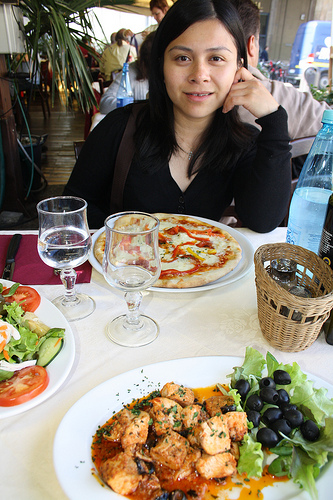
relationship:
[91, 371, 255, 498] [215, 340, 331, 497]
chicken dish with salad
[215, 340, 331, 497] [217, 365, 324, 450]
salad and black olives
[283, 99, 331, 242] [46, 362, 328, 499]
bottle on table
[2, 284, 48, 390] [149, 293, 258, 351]
salad on table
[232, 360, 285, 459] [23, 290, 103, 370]
lettuce on plate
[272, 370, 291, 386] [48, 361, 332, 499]
olive on plate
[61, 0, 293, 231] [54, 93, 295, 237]
woman in black shirt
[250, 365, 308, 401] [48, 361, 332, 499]
lettuce on plate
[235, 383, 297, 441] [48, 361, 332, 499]
olives on plate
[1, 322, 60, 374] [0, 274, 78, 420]
salad on plate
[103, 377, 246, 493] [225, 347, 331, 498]
chicken on herbs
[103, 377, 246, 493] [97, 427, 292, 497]
chicken on sauce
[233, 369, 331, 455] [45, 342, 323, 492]
olives on plate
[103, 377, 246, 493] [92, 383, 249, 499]
chicken in sauce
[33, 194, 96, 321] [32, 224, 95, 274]
glass has water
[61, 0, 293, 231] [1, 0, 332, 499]
woman eating at restaurant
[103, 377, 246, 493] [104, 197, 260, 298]
chicken on dish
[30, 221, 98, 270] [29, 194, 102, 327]
water in glass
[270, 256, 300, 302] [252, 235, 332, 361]
salt sitting inside basket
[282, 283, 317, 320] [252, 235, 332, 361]
pepper sitting inside basket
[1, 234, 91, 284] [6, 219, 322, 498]
red napkin lying on table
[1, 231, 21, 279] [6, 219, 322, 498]
knife lying on table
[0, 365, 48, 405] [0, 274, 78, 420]
tomato lying on plate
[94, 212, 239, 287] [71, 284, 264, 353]
pizza on table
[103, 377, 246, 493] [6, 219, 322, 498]
chicken on table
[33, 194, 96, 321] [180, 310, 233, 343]
glass on table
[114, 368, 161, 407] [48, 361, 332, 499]
green herb on plate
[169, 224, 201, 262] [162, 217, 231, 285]
peppers on pizza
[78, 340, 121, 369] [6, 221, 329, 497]
line on tablecloth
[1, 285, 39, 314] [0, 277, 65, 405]
tomato in salad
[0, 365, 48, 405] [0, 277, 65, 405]
tomato in salad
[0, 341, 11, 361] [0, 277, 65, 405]
carrot in salad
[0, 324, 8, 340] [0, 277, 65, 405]
carrot in salad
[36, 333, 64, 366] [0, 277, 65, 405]
cucumber in salad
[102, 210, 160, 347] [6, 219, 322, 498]
empty glass on table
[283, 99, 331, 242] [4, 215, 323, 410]
bottle on table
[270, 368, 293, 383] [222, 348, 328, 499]
olives on lettuce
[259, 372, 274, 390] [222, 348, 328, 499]
olives on lettuce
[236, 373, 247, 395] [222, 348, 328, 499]
olives on lettuce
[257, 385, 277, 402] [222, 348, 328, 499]
olives on lettuce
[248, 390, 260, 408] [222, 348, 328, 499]
olives on lettuce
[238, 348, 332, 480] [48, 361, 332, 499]
herb on plate